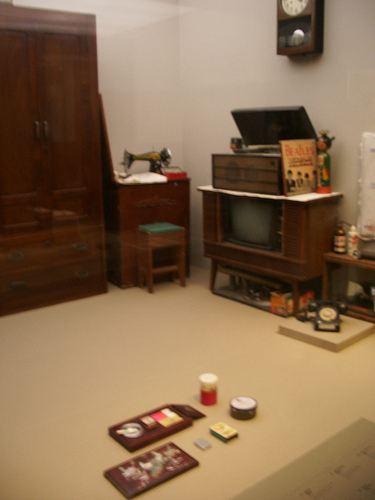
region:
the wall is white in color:
[164, 30, 245, 82]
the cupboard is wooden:
[88, 159, 100, 225]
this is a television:
[219, 200, 262, 264]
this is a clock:
[263, 3, 318, 51]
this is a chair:
[148, 218, 192, 282]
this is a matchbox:
[216, 423, 253, 452]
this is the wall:
[158, 9, 289, 132]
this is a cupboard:
[9, 34, 107, 257]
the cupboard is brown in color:
[20, 91, 69, 170]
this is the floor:
[85, 313, 151, 345]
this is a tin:
[197, 370, 225, 396]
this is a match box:
[207, 416, 238, 441]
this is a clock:
[283, 0, 299, 19]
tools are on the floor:
[105, 369, 252, 477]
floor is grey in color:
[82, 325, 187, 395]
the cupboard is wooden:
[8, 53, 116, 298]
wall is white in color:
[139, 53, 210, 101]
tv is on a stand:
[218, 197, 287, 258]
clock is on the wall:
[271, 4, 324, 54]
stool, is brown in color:
[135, 201, 200, 269]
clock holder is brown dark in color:
[260, 9, 340, 60]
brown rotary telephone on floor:
[293, 295, 347, 332]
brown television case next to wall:
[195, 176, 345, 317]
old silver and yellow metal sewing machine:
[119, 145, 174, 182]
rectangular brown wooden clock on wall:
[275, 0, 326, 55]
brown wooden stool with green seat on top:
[133, 217, 189, 295]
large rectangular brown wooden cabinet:
[0, 1, 111, 322]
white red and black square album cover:
[277, 137, 319, 195]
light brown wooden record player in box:
[207, 100, 319, 195]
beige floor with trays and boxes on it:
[0, 257, 373, 498]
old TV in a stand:
[200, 177, 321, 320]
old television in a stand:
[185, 171, 315, 317]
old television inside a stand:
[201, 181, 315, 317]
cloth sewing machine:
[113, 135, 180, 175]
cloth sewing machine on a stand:
[112, 132, 197, 292]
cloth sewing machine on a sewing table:
[105, 128, 202, 289]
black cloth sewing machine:
[115, 143, 196, 297]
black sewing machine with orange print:
[120, 143, 176, 178]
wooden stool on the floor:
[137, 218, 191, 298]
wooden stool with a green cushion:
[135, 218, 193, 303]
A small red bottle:
[192, 370, 225, 411]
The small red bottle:
[199, 365, 223, 408]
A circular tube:
[225, 394, 265, 422]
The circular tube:
[224, 390, 265, 420]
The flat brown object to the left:
[104, 400, 209, 446]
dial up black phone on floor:
[307, 297, 348, 336]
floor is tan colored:
[0, 252, 373, 466]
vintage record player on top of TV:
[198, 102, 321, 197]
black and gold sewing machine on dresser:
[118, 140, 174, 180]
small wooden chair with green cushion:
[136, 219, 187, 295]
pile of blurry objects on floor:
[96, 368, 259, 497]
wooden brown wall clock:
[272, 0, 325, 62]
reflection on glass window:
[21, 192, 181, 271]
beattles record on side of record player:
[273, 131, 322, 201]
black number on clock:
[299, 2, 304, 9]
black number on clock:
[293, 7, 298, 15]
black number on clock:
[288, 4, 293, 17]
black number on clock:
[285, 2, 291, 8]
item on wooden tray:
[157, 413, 182, 425]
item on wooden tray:
[159, 406, 172, 417]